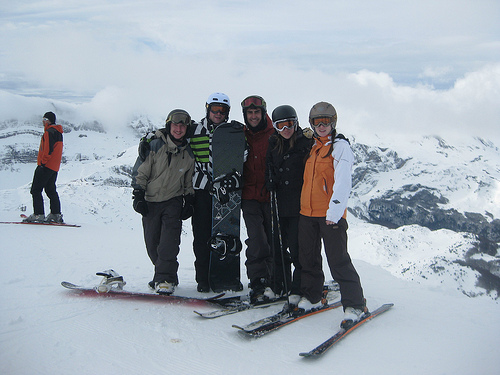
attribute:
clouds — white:
[53, 52, 168, 109]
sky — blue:
[82, 124, 128, 148]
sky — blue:
[1, 0, 499, 101]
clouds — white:
[2, 2, 499, 142]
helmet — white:
[204, 90, 231, 115]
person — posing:
[130, 107, 192, 292]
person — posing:
[189, 92, 244, 292]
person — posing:
[238, 96, 276, 302]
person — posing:
[265, 104, 312, 301]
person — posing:
[295, 102, 369, 326]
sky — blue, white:
[0, 2, 499, 135]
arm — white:
[323, 138, 355, 222]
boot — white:
[294, 296, 326, 316]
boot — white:
[338, 305, 368, 329]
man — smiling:
[130, 108, 195, 295]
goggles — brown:
[163, 109, 193, 125]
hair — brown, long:
[273, 134, 301, 149]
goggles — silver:
[270, 116, 295, 131]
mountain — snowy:
[348, 129, 499, 302]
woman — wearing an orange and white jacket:
[291, 101, 368, 328]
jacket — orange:
[298, 132, 354, 221]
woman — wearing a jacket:
[301, 93, 361, 313]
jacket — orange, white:
[308, 139, 361, 230]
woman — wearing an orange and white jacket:
[298, 94, 391, 328]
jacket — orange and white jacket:
[302, 140, 361, 225]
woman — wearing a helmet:
[304, 90, 372, 321]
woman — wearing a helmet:
[306, 96, 369, 334]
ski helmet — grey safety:
[305, 99, 340, 117]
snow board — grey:
[65, 266, 245, 306]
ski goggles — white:
[270, 118, 297, 129]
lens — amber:
[277, 121, 290, 122]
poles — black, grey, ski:
[263, 183, 295, 307]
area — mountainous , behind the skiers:
[93, 30, 433, 94]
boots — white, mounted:
[289, 292, 326, 310]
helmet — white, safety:
[197, 88, 228, 109]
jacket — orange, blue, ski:
[28, 121, 76, 179]